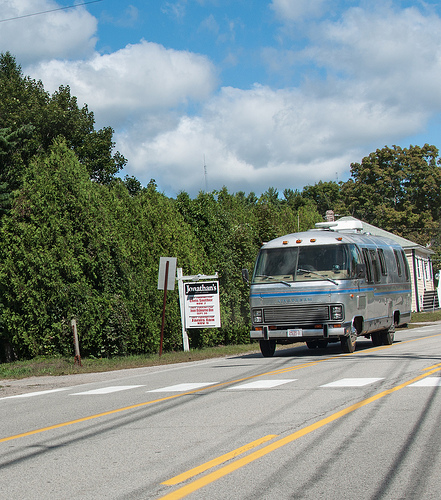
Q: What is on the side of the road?
A: Signs.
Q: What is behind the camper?
A: A house.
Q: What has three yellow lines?
A: A road.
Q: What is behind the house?
A: Trees.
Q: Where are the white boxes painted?
A: On the road.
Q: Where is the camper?
A: On the road.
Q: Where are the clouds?
A: In the sky.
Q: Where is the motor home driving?
A: Down the road.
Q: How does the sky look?
A: Partly cloudy.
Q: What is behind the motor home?
A: A house.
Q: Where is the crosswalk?
A: On the road.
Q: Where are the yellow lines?
A: On the road.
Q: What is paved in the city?
A: A street.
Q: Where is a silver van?
A: A street.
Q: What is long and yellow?
A: A painted line.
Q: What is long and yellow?
A: A painted line.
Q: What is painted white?
A: A cross walk.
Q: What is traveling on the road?
A: A van.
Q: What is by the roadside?
A: Trees.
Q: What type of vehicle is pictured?
A: RV.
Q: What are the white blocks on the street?
A: Crosswalk.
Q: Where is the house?
A: Behind the RV.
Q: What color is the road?
A: Gray.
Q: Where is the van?
A: On the road.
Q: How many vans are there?
A: One.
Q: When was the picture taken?
A: Daytime.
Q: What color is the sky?
A: Blue.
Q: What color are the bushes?
A: Green.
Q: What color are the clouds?
A: White.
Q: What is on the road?
A: The van.